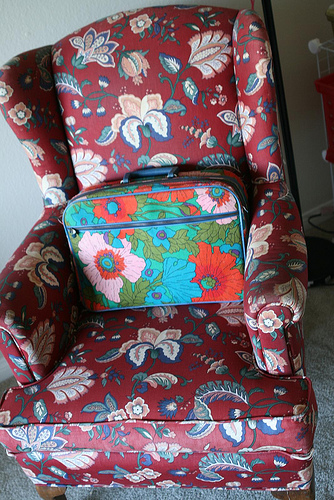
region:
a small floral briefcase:
[62, 168, 248, 308]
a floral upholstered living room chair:
[0, 1, 315, 499]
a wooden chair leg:
[35, 483, 66, 498]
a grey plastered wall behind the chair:
[0, 1, 71, 33]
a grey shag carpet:
[315, 375, 333, 498]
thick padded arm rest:
[245, 185, 306, 377]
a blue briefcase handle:
[120, 165, 176, 185]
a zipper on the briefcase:
[66, 211, 245, 232]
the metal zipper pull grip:
[241, 202, 248, 215]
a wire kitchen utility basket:
[306, 36, 333, 165]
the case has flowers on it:
[56, 165, 255, 319]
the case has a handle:
[117, 164, 176, 184]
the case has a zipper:
[76, 202, 240, 238]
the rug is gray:
[316, 349, 333, 478]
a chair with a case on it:
[5, 17, 315, 488]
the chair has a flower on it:
[121, 326, 185, 366]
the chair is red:
[13, 383, 308, 454]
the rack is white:
[303, 33, 332, 169]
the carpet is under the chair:
[86, 489, 252, 497]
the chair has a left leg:
[32, 484, 72, 498]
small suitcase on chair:
[0, 4, 314, 497]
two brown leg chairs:
[35, 478, 319, 498]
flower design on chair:
[123, 326, 181, 369]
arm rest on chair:
[242, 185, 308, 370]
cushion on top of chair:
[2, 304, 317, 451]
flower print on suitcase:
[72, 186, 244, 312]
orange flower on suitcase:
[190, 244, 242, 302]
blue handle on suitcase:
[121, 164, 178, 183]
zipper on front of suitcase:
[68, 209, 235, 236]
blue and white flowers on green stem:
[70, 76, 113, 117]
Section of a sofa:
[228, 14, 281, 171]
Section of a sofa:
[187, 375, 318, 466]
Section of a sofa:
[12, 388, 159, 462]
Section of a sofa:
[4, 242, 71, 388]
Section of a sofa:
[105, 44, 187, 175]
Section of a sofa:
[62, 161, 258, 323]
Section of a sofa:
[2, 49, 90, 198]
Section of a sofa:
[108, 157, 240, 205]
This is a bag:
[52, 158, 251, 328]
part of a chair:
[143, 373, 171, 429]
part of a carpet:
[191, 486, 196, 490]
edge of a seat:
[167, 396, 178, 412]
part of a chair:
[278, 327, 287, 344]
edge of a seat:
[297, 415, 304, 432]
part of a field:
[161, 422, 167, 431]